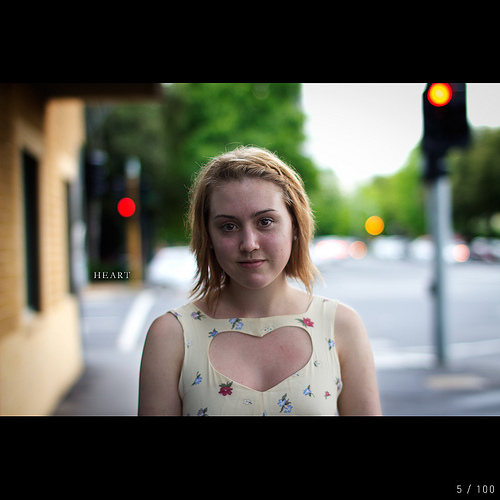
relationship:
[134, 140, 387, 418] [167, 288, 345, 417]
woman has dress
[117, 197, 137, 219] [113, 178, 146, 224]
traffic light of traffic light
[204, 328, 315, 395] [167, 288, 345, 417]
heart on dress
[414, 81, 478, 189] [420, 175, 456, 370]
traffic light has pole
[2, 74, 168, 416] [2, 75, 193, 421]
building on side of woman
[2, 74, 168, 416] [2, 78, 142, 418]
building on left side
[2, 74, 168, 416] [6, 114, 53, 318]
building has window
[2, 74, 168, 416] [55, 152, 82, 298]
building has window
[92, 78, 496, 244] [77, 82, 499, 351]
trees in background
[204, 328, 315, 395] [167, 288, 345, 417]
pattern in woman's top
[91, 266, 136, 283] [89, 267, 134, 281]
word in capital letters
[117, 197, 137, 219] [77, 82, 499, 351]
traffic light in background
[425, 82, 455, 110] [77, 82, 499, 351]
light in background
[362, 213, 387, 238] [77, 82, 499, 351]
light in background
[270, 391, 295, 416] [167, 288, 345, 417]
flower pattern on woman's top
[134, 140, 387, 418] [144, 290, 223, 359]
woman has woman's shoulder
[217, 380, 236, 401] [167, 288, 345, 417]
flower on woman's top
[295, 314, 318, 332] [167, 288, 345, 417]
flower on woman's top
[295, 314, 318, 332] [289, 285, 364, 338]
flower on shoulder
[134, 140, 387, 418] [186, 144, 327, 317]
woman has hair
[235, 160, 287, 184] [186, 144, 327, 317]
braid in hair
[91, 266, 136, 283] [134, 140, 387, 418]
word next to woman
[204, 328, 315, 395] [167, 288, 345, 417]
heart in her dress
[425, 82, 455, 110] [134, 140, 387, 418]
light closest to girl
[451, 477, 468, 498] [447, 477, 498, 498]
5 part of shutter speed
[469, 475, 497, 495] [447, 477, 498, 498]
100 part of shutter speed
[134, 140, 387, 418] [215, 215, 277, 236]
woman has woman's eyes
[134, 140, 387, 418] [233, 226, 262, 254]
woman has a nose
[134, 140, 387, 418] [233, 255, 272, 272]
woman has a mouth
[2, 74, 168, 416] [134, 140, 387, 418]
building beside woman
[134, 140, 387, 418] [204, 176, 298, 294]
woman has a face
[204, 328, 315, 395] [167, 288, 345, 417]
shape in girl's dress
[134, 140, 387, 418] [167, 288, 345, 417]
girl wearing dress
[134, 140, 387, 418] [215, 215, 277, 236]
woman has two eyes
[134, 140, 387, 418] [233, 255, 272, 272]
girl has a mouth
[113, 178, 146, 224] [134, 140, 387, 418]
traffic light behind girl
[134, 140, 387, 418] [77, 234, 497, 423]
girl near street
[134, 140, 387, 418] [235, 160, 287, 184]
girl has braid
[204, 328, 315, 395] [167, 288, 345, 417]
heart cutout in shirt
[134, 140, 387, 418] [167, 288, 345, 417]
girl in in shirt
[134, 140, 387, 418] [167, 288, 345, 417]
woman has a shirt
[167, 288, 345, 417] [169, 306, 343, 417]
shirt has flowers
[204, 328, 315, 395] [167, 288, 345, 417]
heart cut out in shirt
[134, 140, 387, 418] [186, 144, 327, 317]
girl has hair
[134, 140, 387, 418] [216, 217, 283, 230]
girl has eyes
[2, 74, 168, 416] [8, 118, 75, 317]
building has windows